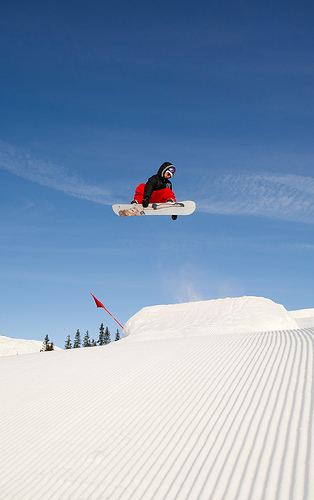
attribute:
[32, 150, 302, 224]
clouds — wispy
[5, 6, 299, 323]
sky — blue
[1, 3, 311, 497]
scene — outdoors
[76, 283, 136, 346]
flag — red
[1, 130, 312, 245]
clouds — white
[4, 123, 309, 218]
clouds — white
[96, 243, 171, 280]
clouds — white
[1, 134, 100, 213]
clouds — white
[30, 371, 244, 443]
snow — white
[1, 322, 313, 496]
side — hill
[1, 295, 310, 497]
side — hill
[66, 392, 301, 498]
snow — white